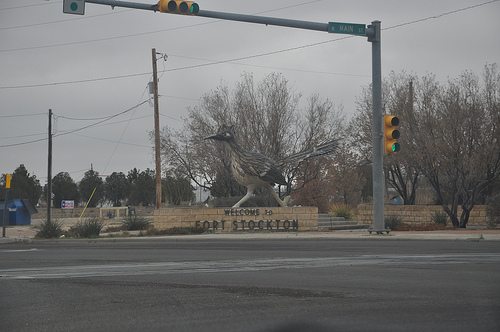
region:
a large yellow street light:
[382, 112, 406, 155]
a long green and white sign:
[323, 19, 370, 34]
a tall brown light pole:
[150, 45, 174, 206]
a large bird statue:
[208, 125, 345, 210]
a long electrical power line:
[158, 33, 360, 76]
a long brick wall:
[356, 198, 491, 227]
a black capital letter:
[238, 213, 249, 233]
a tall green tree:
[78, 165, 107, 204]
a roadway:
[2, 237, 498, 330]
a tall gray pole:
[371, 20, 399, 229]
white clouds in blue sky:
[7, 17, 64, 65]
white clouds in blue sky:
[12, 64, 69, 97]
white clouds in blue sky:
[70, 108, 130, 150]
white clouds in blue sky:
[55, 57, 102, 92]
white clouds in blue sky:
[98, 24, 131, 77]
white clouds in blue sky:
[177, 33, 228, 61]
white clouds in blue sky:
[413, 10, 477, 56]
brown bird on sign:
[205, 126, 283, 197]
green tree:
[412, 96, 498, 165]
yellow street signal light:
[381, 104, 402, 168]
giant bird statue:
[198, 113, 347, 215]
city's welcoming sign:
[152, 200, 320, 237]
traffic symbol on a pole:
[379, 109, 405, 161]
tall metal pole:
[368, 16, 393, 238]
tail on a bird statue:
[276, 128, 348, 174]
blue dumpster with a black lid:
[2, 195, 38, 233]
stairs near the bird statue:
[311, 205, 373, 236]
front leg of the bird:
[218, 179, 265, 213]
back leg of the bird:
[263, 183, 298, 215]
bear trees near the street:
[139, 59, 494, 235]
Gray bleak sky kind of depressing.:
[11, 3, 496, 223]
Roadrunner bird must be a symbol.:
[203, 118, 343, 209]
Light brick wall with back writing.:
[149, 205, 324, 237]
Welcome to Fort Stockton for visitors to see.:
[190, 204, 310, 236]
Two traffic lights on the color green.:
[156, 1, 403, 156]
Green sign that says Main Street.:
[325, 15, 370, 35]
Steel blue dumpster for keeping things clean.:
[3, 195, 40, 231]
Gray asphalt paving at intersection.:
[11, 234, 496, 325]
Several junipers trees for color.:
[1, 160, 203, 211]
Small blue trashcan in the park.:
[389, 191, 407, 207]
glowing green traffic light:
[387, 139, 399, 152]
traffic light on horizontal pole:
[155, 0, 385, 37]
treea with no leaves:
[382, 74, 494, 225]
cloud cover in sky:
[2, 0, 498, 177]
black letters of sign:
[193, 206, 300, 231]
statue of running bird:
[205, 125, 338, 205]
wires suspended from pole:
[3, 48, 161, 221]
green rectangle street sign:
[327, 21, 367, 36]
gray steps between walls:
[305, 205, 372, 232]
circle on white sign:
[62, 0, 86, 15]